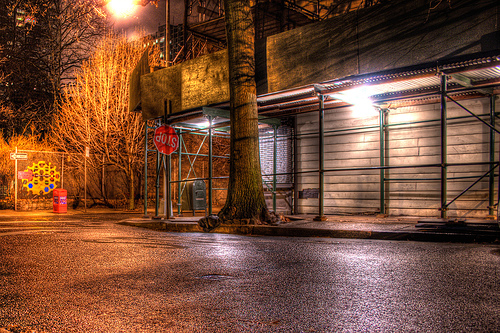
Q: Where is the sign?
A: On the fence.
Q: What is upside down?
A: A Stop Sign.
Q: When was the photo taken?
A: Nighttime.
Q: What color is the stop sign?
A: Red.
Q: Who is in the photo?
A: Nobody.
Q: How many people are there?
A: Zero.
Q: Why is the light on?
A: It is dark outside.